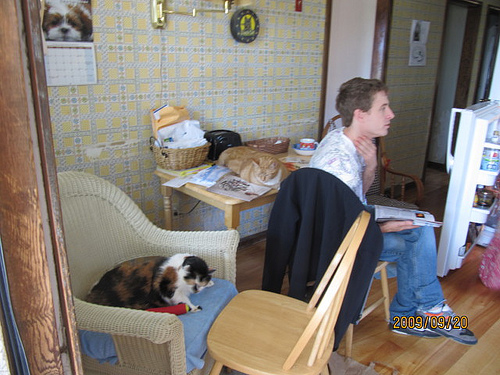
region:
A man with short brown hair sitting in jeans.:
[306, 77, 477, 344]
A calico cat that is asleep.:
[83, 252, 219, 311]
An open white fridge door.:
[438, 99, 498, 278]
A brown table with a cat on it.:
[154, 143, 317, 245]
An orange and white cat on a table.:
[218, 143, 291, 188]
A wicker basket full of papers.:
[147, 134, 210, 166]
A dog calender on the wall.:
[38, 1, 100, 86]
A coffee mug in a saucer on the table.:
[292, 138, 319, 154]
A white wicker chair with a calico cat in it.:
[57, 169, 239, 373]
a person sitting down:
[324, 68, 471, 348]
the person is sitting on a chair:
[299, 74, 479, 359]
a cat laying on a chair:
[79, 256, 216, 319]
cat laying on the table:
[213, 142, 293, 195]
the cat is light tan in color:
[220, 145, 288, 191]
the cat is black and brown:
[91, 247, 218, 314]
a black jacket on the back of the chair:
[248, 171, 381, 311]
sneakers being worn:
[390, 300, 485, 348]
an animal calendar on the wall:
[35, 0, 109, 82]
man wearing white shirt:
[290, 68, 484, 364]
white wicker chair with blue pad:
[57, 170, 228, 372]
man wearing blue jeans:
[316, 73, 464, 346]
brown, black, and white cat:
[81, 243, 221, 314]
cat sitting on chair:
[87, 238, 207, 318]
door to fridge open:
[446, 83, 488, 290]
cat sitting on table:
[222, 138, 282, 190]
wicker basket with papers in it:
[144, 108, 210, 174]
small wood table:
[167, 108, 327, 222]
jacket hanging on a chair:
[257, 173, 387, 329]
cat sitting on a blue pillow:
[84, 228, 207, 323]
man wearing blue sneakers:
[389, 290, 476, 351]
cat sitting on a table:
[211, 133, 291, 196]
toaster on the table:
[201, 115, 247, 154]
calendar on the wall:
[39, 3, 104, 89]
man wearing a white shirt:
[307, 113, 379, 217]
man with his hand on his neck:
[343, 133, 383, 189]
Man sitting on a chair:
[310, 76, 478, 345]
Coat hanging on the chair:
[260, 167, 385, 352]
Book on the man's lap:
[373, 200, 444, 229]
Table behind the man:
[152, 147, 320, 231]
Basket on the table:
[148, 137, 210, 169]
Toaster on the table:
[205, 129, 242, 162]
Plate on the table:
[293, 143, 316, 156]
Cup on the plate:
[296, 137, 318, 149]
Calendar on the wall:
[41, 0, 99, 86]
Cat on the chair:
[83, 250, 215, 312]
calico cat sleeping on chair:
[81, 252, 215, 313]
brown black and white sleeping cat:
[83, 253, 215, 311]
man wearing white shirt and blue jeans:
[308, 77, 473, 344]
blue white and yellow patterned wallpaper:
[47, 0, 446, 239]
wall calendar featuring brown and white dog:
[41, 0, 98, 83]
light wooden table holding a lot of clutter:
[149, 104, 319, 229]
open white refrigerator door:
[435, 100, 499, 276]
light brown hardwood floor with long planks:
[233, 167, 498, 372]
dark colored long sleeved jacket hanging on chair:
[261, 167, 390, 358]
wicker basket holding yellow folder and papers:
[149, 102, 210, 169]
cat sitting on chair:
[87, 238, 224, 330]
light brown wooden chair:
[195, 212, 389, 372]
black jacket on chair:
[256, 160, 393, 334]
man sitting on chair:
[317, 69, 476, 364]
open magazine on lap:
[370, 198, 447, 230]